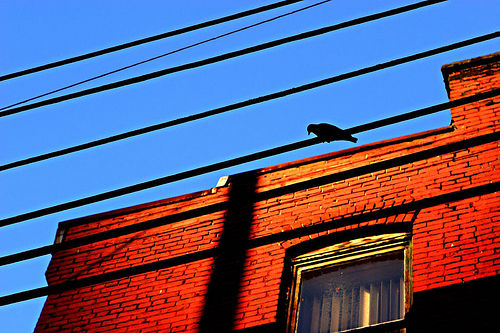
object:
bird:
[307, 123, 358, 144]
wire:
[0, 67, 499, 307]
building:
[34, 50, 500, 333]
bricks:
[31, 53, 500, 333]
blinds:
[299, 275, 403, 332]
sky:
[0, 0, 500, 333]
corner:
[57, 218, 85, 237]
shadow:
[196, 171, 499, 333]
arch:
[283, 219, 413, 258]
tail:
[350, 137, 358, 144]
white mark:
[216, 176, 230, 187]